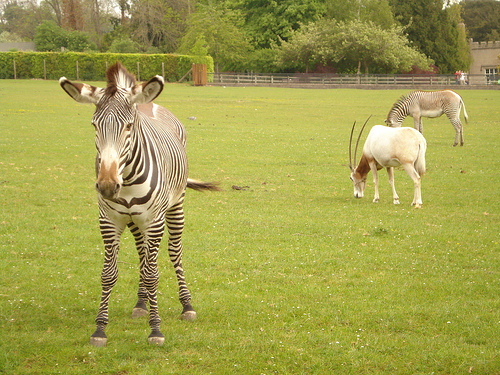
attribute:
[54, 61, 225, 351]
zebra — black, white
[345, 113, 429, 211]
animal — white, african, feeding, grazing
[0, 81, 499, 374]
grass — green, grassy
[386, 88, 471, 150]
zebra — grazing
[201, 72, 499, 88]
fence — long, wooden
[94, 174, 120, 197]
snout — brown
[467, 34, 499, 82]
building — small, castle like, tan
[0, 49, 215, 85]
hedge — green, trimmed, well manicured, manicured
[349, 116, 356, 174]
horn — long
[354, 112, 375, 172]
horn — long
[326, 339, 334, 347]
flower — white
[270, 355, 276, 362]
flower — white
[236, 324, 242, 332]
flower — white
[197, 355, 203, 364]
flower — white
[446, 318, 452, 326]
flower — white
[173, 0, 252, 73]
tree — large